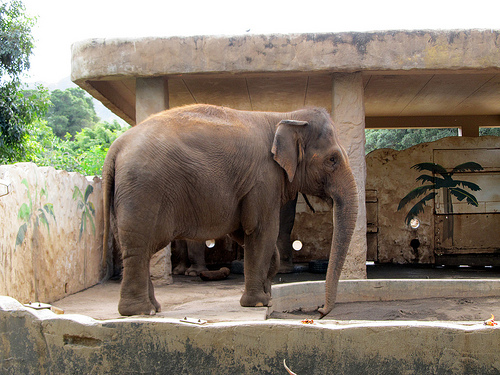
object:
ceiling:
[94, 71, 499, 126]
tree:
[0, 0, 35, 166]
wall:
[2, 295, 498, 374]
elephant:
[100, 103, 357, 316]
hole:
[290, 238, 306, 251]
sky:
[2, 0, 497, 126]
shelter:
[67, 30, 498, 275]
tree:
[0, 0, 39, 161]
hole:
[203, 236, 216, 250]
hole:
[405, 218, 421, 230]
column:
[327, 70, 370, 279]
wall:
[180, 132, 499, 276]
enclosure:
[0, 143, 498, 373]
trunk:
[312, 162, 360, 313]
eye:
[327, 152, 339, 166]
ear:
[269, 118, 308, 183]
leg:
[238, 189, 285, 307]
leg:
[115, 188, 162, 315]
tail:
[98, 143, 111, 266]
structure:
[70, 31, 499, 279]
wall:
[2, 160, 108, 305]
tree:
[398, 159, 484, 257]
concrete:
[269, 280, 499, 309]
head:
[269, 103, 358, 210]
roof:
[66, 28, 499, 79]